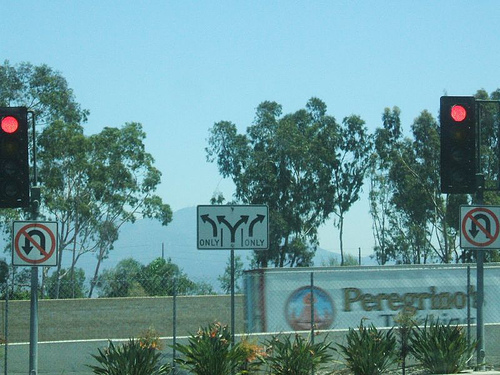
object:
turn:
[198, 214, 222, 236]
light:
[447, 103, 469, 122]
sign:
[195, 198, 275, 254]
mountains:
[0, 205, 357, 298]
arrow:
[247, 213, 267, 238]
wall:
[0, 294, 247, 344]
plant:
[82, 322, 181, 375]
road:
[0, 325, 500, 375]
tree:
[204, 89, 339, 271]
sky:
[0, 0, 500, 294]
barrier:
[243, 263, 500, 334]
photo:
[0, 0, 500, 375]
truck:
[53, 223, 67, 296]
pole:
[474, 245, 485, 371]